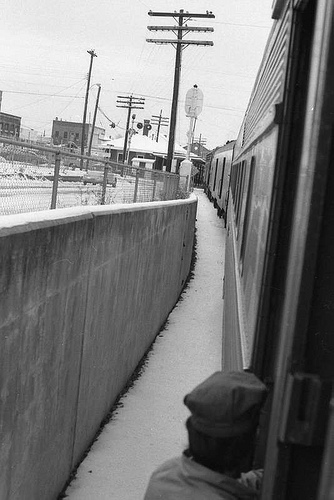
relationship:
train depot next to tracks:
[97, 118, 203, 186] [202, 187, 230, 256]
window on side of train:
[217, 158, 227, 198] [186, 0, 332, 498]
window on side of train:
[212, 158, 218, 190] [186, 0, 332, 498]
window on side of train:
[207, 158, 211, 186] [186, 0, 332, 498]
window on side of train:
[239, 156, 255, 264] [186, 0, 332, 498]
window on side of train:
[235, 157, 246, 241] [186, 0, 332, 498]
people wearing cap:
[142, 367, 270, 500] [177, 363, 272, 447]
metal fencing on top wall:
[3, 149, 184, 203] [5, 200, 198, 497]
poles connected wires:
[68, 11, 216, 171] [1, 9, 228, 111]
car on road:
[82, 161, 117, 187] [0, 176, 165, 217]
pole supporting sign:
[185, 116, 196, 159] [186, 86, 204, 116]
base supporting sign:
[179, 159, 194, 186] [186, 86, 204, 116]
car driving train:
[82, 161, 117, 187] [196, 1, 323, 488]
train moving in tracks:
[201, 0, 331, 497] [201, 187, 244, 256]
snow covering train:
[55, 190, 223, 494] [260, 69, 312, 225]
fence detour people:
[14, 139, 72, 201] [129, 362, 275, 491]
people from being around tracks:
[129, 362, 275, 491] [202, 187, 230, 256]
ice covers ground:
[110, 429, 151, 457] [186, 302, 217, 351]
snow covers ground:
[82, 211, 221, 498] [186, 302, 217, 351]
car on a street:
[82, 161, 117, 187] [22, 172, 91, 201]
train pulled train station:
[201, 0, 331, 497] [3, 127, 225, 492]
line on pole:
[143, 52, 150, 64] [161, 77, 183, 141]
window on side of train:
[232, 158, 246, 232] [186, 0, 332, 498]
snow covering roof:
[106, 134, 176, 152] [99, 134, 208, 162]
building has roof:
[102, 131, 209, 183] [99, 134, 208, 162]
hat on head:
[176, 359, 273, 422] [146, 344, 283, 468]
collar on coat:
[180, 447, 256, 495] [141, 447, 265, 499]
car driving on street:
[76, 158, 123, 186] [16, 182, 178, 201]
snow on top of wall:
[145, 193, 173, 205] [127, 203, 204, 290]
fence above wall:
[0, 135, 189, 213] [10, 196, 197, 330]